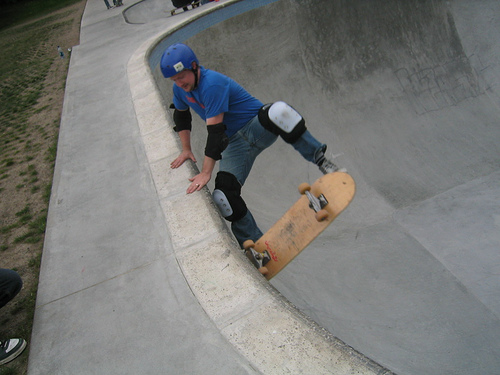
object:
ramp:
[149, 0, 499, 374]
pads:
[258, 99, 308, 143]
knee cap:
[212, 181, 235, 217]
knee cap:
[260, 102, 302, 132]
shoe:
[0, 333, 27, 366]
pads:
[210, 171, 245, 222]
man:
[161, 43, 348, 248]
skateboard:
[243, 170, 355, 281]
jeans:
[216, 103, 339, 245]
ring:
[195, 184, 198, 187]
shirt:
[170, 67, 265, 140]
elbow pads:
[204, 123, 230, 161]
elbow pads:
[169, 103, 192, 132]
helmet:
[159, 42, 200, 89]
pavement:
[25, 0, 497, 373]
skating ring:
[158, 42, 359, 280]